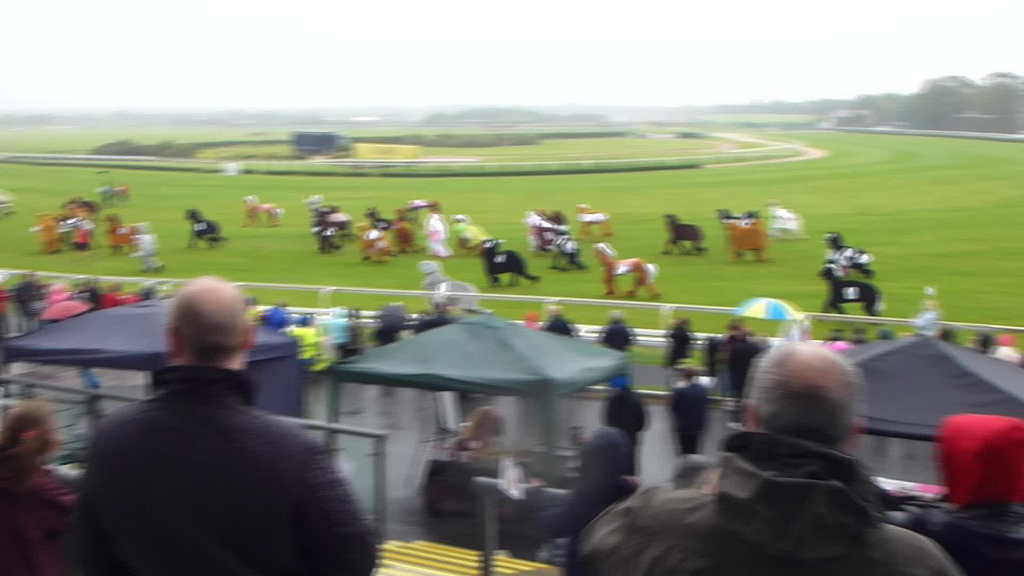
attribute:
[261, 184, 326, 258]
horse — light brown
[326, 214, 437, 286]
horse — light brown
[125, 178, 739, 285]
horses — running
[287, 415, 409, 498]
rail — grey